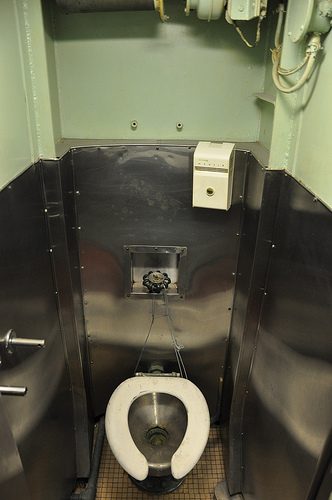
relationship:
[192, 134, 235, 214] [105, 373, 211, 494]
box above toilet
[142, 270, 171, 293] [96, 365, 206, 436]
valve for toilet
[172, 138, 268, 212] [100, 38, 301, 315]
dispenser on wall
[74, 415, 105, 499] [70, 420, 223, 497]
pipe running along floor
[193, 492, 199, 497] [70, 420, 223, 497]
tile on floor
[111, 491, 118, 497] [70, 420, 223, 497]
tile on floor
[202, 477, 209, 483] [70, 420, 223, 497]
tile on floor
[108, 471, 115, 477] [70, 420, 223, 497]
tile on floor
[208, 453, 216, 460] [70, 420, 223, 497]
tile on floor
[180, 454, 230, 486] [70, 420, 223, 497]
tile on floor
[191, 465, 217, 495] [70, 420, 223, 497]
tile on floor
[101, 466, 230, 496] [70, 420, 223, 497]
tile on floor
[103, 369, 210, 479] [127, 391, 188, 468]
toilet seat covering bowl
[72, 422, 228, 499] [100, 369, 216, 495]
tile underneath toilet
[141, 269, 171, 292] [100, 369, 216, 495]
valve over toilet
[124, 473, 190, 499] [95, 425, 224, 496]
base attached to floor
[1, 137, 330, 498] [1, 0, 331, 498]
wall of bathroom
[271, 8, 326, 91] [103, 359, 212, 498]
plumbing pipes for toilet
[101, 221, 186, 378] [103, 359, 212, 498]
equipment for toilet